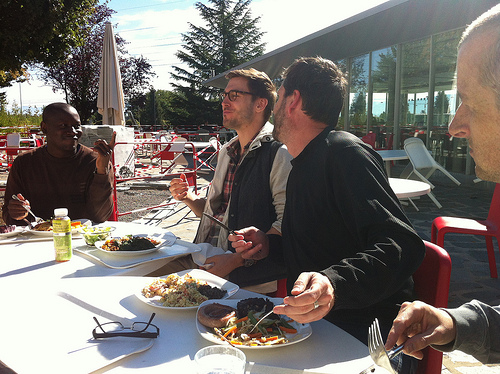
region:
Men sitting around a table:
[1, 1, 499, 370]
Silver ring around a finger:
[308, 293, 323, 316]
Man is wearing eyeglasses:
[212, 65, 276, 134]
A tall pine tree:
[164, 0, 270, 126]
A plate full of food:
[134, 270, 240, 313]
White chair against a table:
[373, 132, 464, 212]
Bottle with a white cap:
[48, 204, 73, 264]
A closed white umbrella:
[93, 17, 131, 127]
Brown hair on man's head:
[267, 53, 348, 149]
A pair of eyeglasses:
[84, 311, 165, 345]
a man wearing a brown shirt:
[3, 101, 115, 223]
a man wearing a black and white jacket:
[168, 67, 292, 292]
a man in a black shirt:
[225, 57, 427, 324]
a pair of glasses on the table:
[91, 310, 159, 338]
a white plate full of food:
[196, 298, 313, 348]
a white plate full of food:
[134, 274, 239, 308]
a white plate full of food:
[93, 235, 164, 255]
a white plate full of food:
[23, 219, 92, 236]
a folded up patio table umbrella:
[97, 40, 124, 127]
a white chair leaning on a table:
[403, 140, 460, 210]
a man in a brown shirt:
[1, 101, 118, 225]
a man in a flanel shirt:
[168, 64, 293, 277]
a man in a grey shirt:
[379, 2, 499, 364]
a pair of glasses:
[87, 309, 162, 340]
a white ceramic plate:
[195, 296, 313, 347]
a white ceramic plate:
[133, 264, 238, 311]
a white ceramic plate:
[96, 230, 166, 255]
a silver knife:
[202, 212, 237, 235]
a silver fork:
[366, 319, 402, 372]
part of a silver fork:
[367, 313, 402, 373]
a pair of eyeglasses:
[92, 312, 162, 339]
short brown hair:
[227, 66, 276, 115]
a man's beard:
[220, 97, 259, 127]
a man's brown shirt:
[2, 143, 111, 218]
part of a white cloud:
[129, 10, 196, 37]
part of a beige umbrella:
[95, 20, 130, 122]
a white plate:
[92, 235, 161, 255]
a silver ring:
[312, 298, 322, 313]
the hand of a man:
[385, 288, 453, 355]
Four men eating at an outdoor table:
[0, 5, 498, 370]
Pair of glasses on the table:
[90, 313, 160, 343]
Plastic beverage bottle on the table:
[52, 205, 72, 264]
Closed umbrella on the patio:
[95, 17, 126, 137]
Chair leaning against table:
[402, 133, 458, 208]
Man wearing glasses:
[216, 63, 274, 152]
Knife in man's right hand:
[198, 208, 279, 258]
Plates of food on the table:
[31, 212, 295, 352]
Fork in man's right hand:
[13, 194, 49, 226]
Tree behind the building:
[170, 0, 268, 184]